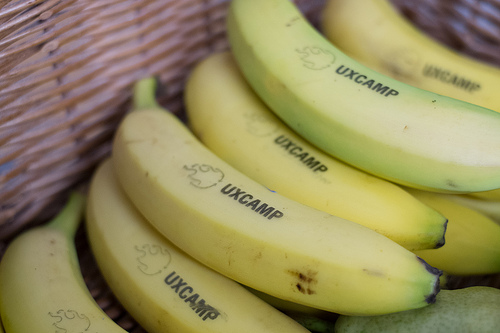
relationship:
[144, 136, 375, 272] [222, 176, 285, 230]
banana has lettering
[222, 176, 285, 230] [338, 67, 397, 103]
lettering says uxcamp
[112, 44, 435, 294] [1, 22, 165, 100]
bananas in basket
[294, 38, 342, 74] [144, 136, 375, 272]
design on banana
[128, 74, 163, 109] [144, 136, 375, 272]
stem on banana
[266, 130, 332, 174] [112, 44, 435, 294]
stamps on bananas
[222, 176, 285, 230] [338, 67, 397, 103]
lettering say uxcamp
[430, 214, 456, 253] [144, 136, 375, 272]
bottom of banana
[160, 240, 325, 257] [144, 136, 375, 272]
skin of banana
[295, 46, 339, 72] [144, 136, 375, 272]
design on banana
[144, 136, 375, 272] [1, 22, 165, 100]
banana in basket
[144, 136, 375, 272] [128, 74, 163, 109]
banana has top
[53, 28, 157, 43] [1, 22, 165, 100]
grooves in basket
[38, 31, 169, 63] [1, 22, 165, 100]
lines on basket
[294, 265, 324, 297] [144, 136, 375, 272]
spots on banana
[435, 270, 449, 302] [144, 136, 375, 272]
tip on banana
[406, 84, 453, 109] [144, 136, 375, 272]
spot on banana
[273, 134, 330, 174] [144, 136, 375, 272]
stamps on banana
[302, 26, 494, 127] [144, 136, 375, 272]
edge on banana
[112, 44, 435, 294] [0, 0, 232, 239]
bananas in basket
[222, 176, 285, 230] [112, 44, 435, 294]
name on bananas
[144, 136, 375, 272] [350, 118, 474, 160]
banana has peel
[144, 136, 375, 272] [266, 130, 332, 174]
banana has stamps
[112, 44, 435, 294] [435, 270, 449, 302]
bananas has tip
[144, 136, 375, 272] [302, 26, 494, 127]
banana has edge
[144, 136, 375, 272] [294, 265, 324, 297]
banana has spots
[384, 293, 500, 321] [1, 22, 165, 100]
stone in basket